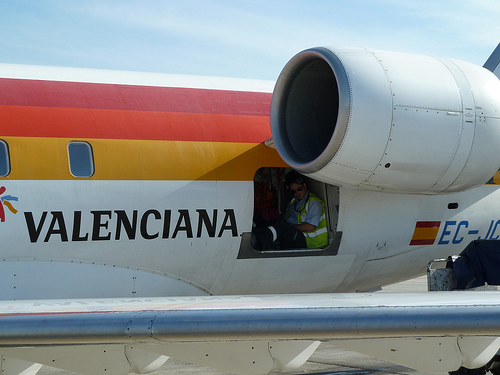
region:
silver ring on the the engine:
[263, 44, 354, 168]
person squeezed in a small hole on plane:
[248, 168, 334, 258]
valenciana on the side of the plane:
[20, 205, 245, 251]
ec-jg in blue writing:
[439, 212, 497, 252]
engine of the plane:
[266, 47, 498, 212]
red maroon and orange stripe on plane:
[1, 60, 268, 212]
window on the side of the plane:
[68, 135, 95, 176]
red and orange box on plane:
[405, 210, 442, 252]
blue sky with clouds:
[3, 0, 484, 62]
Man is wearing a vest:
[276, 190, 336, 250]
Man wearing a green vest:
[280, 190, 335, 251]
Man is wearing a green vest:
[280, 190, 332, 250]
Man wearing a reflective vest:
[283, 190, 330, 248]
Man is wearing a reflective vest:
[280, 190, 334, 251]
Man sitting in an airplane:
[251, 177, 333, 254]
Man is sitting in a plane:
[242, 163, 343, 253]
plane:
[7, 31, 494, 293]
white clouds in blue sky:
[21, 2, 76, 44]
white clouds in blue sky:
[54, 25, 102, 63]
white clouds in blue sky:
[418, 3, 465, 30]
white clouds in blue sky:
[338, 5, 392, 49]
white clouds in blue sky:
[248, 13, 305, 55]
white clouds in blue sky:
[190, 22, 230, 52]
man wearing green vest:
[313, 236, 323, 246]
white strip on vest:
[316, 226, 327, 238]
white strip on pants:
[267, 224, 280, 244]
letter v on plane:
[17, 208, 46, 244]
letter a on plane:
[48, 208, 69, 247]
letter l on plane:
[69, 207, 91, 246]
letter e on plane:
[87, 202, 115, 245]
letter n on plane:
[111, 205, 139, 251]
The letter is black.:
[217, 197, 242, 249]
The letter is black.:
[193, 195, 220, 245]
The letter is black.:
[169, 203, 197, 248]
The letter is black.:
[138, 203, 163, 250]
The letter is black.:
[111, 202, 141, 249]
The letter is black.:
[67, 201, 92, 250]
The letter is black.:
[43, 195, 73, 252]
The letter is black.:
[17, 200, 51, 255]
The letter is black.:
[161, 202, 174, 244]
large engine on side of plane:
[263, 21, 491, 218]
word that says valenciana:
[20, 193, 242, 244]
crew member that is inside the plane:
[258, 174, 329, 253]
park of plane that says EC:
[440, 215, 469, 247]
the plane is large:
[22, 83, 456, 326]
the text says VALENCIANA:
[9, 156, 266, 290]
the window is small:
[56, 116, 134, 195]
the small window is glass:
[56, 124, 141, 182]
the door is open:
[202, 120, 372, 314]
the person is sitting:
[274, 184, 368, 271]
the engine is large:
[258, 88, 429, 197]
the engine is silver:
[274, 63, 394, 172]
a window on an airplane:
[74, 133, 91, 177]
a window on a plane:
[72, 131, 86, 178]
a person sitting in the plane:
[276, 158, 333, 235]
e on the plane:
[436, 218, 458, 248]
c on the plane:
[455, 216, 480, 248]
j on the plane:
[475, 216, 498, 256]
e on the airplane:
[434, 213, 450, 238]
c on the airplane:
[453, 220, 475, 256]